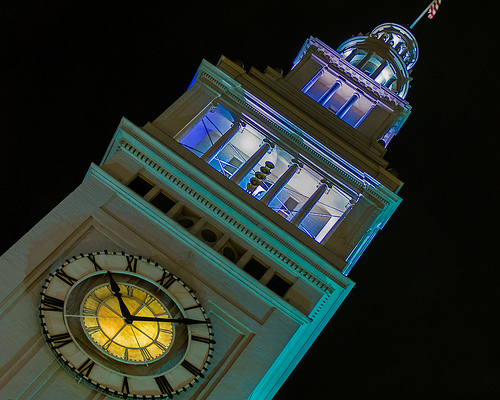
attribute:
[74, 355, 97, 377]
roman numeral — upside down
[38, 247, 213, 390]
clock — yellow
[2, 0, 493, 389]
tower — white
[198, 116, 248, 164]
column — white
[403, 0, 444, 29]
flag — american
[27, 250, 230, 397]
clock — ORNATE, with white face and black roman numeral, yellow, numerals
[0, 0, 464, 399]
clock tower — white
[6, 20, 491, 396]
sky — black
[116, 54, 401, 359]
steeple — ornate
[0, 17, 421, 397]
tower — cylindrical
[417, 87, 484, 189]
sky — black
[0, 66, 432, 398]
tower — tall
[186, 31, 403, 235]
lighting — blue, purple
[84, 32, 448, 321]
tower — white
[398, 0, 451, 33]
flag — US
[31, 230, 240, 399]
clock — yellow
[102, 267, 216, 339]
hands — black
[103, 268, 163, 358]
clock — yellow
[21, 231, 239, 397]
face clock — yellow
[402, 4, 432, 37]
steeple — blue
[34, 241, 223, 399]
clock — little past 10, yellow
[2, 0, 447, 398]
tower — BLUE, high